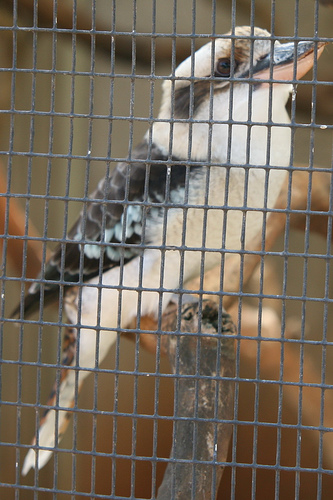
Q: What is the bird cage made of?
A: Metal mesh.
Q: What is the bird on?
A: A small stump.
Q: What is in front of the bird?
A: A small cage.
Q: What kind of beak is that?
A: A small black beak.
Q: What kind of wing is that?
A: A small black wing with blue spots.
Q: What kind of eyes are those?
A: Small brown eyes on a bird.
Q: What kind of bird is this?
A: A small white and black bird.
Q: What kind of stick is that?
A: A small twisted brown stick.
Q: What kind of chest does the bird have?
A: A small white chest.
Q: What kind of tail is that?
A: A small white and brown tail.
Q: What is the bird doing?
A: Standing on a wooden stump.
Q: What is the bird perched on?
A: A branch.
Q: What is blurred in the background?
A: A brown branch.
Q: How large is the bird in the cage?
A: Small.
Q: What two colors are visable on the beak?
A: Black and orange.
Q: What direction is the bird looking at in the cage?
A: Up.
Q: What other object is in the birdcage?
A: A tree branch.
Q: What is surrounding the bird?
A: Metal caging.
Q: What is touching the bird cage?
A: A thick branch.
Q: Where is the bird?
A: Inside a cage.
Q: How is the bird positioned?
A: On a perch.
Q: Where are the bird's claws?
A: Wrapped around the perch.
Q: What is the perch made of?
A: Wood of a branch.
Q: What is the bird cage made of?
A: Metal.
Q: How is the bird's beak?
A: Short and two-toned.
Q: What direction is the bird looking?
A: Up.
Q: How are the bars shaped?
A: In small rectangles.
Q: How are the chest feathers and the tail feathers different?
A: Color.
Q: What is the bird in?
A: A cage.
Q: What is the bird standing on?
A: A twig.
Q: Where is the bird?
A: Cage.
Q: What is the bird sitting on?
A: Branch.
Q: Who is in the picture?
A: No one.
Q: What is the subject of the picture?
A: Bird.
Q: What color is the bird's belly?
A: White.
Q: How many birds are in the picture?
A: One.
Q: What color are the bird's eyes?
A: Brown.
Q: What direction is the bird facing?
A: Right.